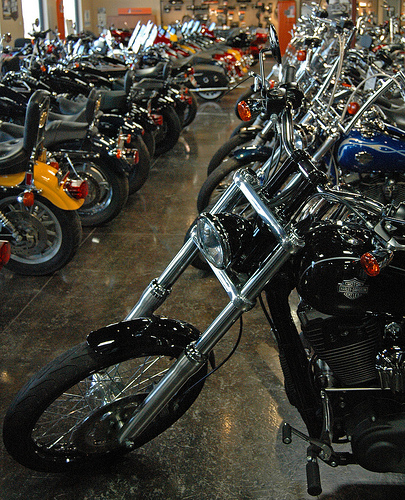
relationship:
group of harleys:
[0, 3, 403, 498] [25, 38, 194, 120]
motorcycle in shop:
[0, 92, 89, 276] [2, 1, 401, 499]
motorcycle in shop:
[32, 89, 124, 230] [2, 1, 401, 499]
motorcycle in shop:
[171, 53, 231, 102] [2, 1, 401, 499]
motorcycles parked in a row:
[0, 0, 256, 272] [0, 0, 254, 278]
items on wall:
[160, 0, 279, 37] [88, 1, 314, 40]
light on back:
[68, 176, 90, 195] [34, 159, 85, 276]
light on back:
[240, 58, 251, 67] [227, 46, 249, 77]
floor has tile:
[0, 76, 405, 499] [11, 268, 161, 324]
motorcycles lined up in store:
[0, 0, 256, 272] [2, 1, 401, 499]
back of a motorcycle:
[227, 46, 249, 77] [223, 44, 251, 83]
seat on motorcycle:
[40, 122, 93, 145] [32, 89, 124, 230]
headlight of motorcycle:
[197, 213, 247, 269] [2, 3, 402, 495]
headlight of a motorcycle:
[197, 213, 247, 269] [2, 3, 402, 495]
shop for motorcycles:
[2, 1, 401, 499] [0, 0, 256, 272]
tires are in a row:
[2, 79, 196, 277] [0, 79, 196, 279]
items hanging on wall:
[160, 0, 279, 37] [88, 1, 314, 40]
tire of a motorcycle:
[4, 341, 209, 475] [2, 3, 402, 495]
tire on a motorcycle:
[0, 188, 82, 277] [0, 92, 89, 276]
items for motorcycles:
[160, 0, 279, 37] [0, 0, 256, 272]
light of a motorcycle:
[68, 176, 90, 195] [0, 92, 89, 276]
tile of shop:
[11, 268, 161, 324] [2, 1, 401, 499]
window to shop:
[20, 0, 44, 39] [2, 1, 401, 499]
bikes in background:
[0, 21, 405, 89] [0, 2, 402, 99]